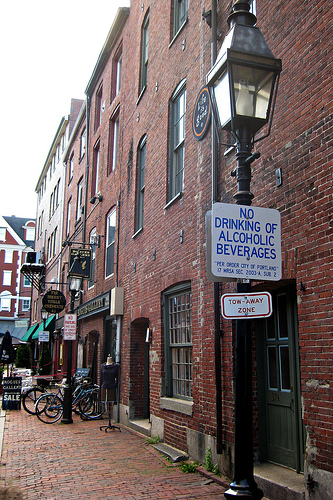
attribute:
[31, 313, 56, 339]
awnings —  green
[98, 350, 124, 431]
mannequin — in the picture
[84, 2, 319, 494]
building — red brick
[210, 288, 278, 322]
sign — red, white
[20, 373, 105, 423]
row — bikes